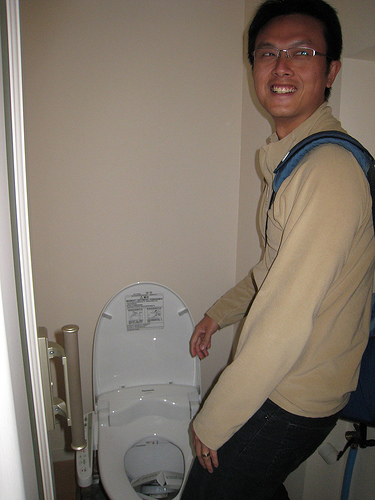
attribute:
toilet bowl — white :
[28, 235, 205, 429]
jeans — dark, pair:
[176, 399, 338, 495]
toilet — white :
[76, 280, 214, 498]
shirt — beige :
[190, 102, 373, 452]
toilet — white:
[87, 283, 206, 492]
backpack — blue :
[264, 129, 373, 459]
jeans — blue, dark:
[192, 397, 342, 498]